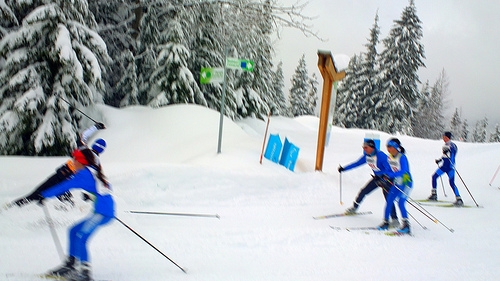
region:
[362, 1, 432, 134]
a tall green tree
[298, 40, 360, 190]
a brown sign post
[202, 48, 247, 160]
a grey sign post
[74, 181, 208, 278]
a black ski pole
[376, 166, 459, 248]
a silver ski pole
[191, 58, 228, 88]
a green arrow sign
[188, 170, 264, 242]
a section of snow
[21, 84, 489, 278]
a white ski slope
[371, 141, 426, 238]
a blue ski suit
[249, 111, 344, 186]
a fabric blue flag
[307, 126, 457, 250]
TWO SKIERS SIDE BY SIDE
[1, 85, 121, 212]
A MAN FALLING IN THE SNOW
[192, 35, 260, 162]
A POST WITH TWO SIGNS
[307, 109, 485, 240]
THREE SKIERS SKIING ON THE FLAT GROUND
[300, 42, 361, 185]
a wooden post with a hanging sign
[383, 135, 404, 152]
a blue head band on a skiier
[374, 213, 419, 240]
a black and blue pair of ski boots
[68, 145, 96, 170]
a red head band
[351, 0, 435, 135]
a snow covered pine tree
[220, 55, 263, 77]
a green, blue, and white sign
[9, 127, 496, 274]
a cross country ski race is in progress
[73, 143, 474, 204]
the skiers are wearing white racing vests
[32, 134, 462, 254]
the skiers are in blue jump siuts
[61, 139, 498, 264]
the skiers are holding ski poles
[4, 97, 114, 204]
a skier is wearing black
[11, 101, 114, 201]
the skier caught an edge and is wiping out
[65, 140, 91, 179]
the skier has a yellow and orange vest on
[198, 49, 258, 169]
directional signs are on the slope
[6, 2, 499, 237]
the trees are heavy with snow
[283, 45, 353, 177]
a yellow pole indicator at the intersection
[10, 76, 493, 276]
People skiing in the snow.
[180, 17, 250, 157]
A pole with two signs on it.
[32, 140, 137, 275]
A woman wearing a blue and white ski outfit.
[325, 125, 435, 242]
Two people are skiing next to each other.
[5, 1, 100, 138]
Snow is on the branches of this tree.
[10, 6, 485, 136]
The trees are covered in snow.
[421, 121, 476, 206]
The person is skiing behind the others.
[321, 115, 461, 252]
The people are holding ski poles.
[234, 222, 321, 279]
Snow is on the ground.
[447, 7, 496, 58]
The sky is gray.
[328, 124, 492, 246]
people with snow skis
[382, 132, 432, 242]
person wearing blue coat and pants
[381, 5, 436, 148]
tree with snow covering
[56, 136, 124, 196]
person with red headband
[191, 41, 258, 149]
green and white signs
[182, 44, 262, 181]
signs posted in snow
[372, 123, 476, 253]
person with ski poles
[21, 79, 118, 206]
person with ski in air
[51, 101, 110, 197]
person wearing orange and black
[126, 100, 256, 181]
mound of snow